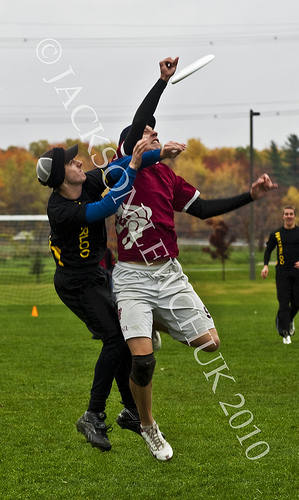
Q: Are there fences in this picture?
A: No, there are no fences.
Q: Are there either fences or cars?
A: No, there are no fences or cars.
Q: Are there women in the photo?
A: No, there are no women.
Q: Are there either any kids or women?
A: No, there are no women or kids.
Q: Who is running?
A: The man is running.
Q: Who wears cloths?
A: The man wears cloths.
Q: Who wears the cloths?
A: The man wears cloths.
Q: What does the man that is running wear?
A: The man wears cloths.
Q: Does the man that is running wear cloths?
A: Yes, the man wears cloths.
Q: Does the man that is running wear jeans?
A: No, the man wears cloths.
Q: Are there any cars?
A: No, there are no cars.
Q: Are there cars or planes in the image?
A: No, there are no cars or planes.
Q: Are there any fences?
A: No, there are no fences.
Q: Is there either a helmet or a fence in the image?
A: No, there are no fences or helmets.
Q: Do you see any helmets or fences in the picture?
A: No, there are no fences or helmets.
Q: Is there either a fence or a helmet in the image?
A: No, there are no fences or helmets.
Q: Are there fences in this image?
A: No, there are no fences.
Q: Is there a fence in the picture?
A: No, there are no fences.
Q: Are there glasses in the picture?
A: No, there are no glasses.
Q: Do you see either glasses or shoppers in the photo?
A: No, there are no glasses or shoppers.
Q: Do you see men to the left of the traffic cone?
A: No, the man is to the right of the traffic cone.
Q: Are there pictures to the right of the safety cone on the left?
A: No, there is a man to the right of the cone.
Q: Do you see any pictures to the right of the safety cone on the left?
A: No, there is a man to the right of the cone.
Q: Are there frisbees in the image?
A: Yes, there is a frisbee.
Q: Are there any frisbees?
A: Yes, there is a frisbee.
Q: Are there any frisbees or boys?
A: Yes, there is a frisbee.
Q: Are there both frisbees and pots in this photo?
A: No, there is a frisbee but no pots.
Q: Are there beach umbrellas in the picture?
A: No, there are no beach umbrellas.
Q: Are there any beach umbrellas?
A: No, there are no beach umbrellas.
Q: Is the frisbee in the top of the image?
A: Yes, the frisbee is in the top of the image.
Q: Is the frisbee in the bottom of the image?
A: No, the frisbee is in the top of the image.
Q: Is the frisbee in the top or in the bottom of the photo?
A: The frisbee is in the top of the image.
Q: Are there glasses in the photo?
A: No, there are no glasses.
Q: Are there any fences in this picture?
A: No, there are no fences.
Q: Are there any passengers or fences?
A: No, there are no fences or passengers.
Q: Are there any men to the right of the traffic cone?
A: Yes, there is a man to the right of the traffic cone.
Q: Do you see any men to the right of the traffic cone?
A: Yes, there is a man to the right of the traffic cone.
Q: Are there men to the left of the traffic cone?
A: No, the man is to the right of the traffic cone.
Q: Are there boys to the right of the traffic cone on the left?
A: No, there is a man to the right of the safety cone.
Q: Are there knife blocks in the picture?
A: No, there are no knife blocks.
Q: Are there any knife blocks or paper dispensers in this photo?
A: No, there are no knife blocks or paper dispensers.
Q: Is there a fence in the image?
A: No, there are no fences.